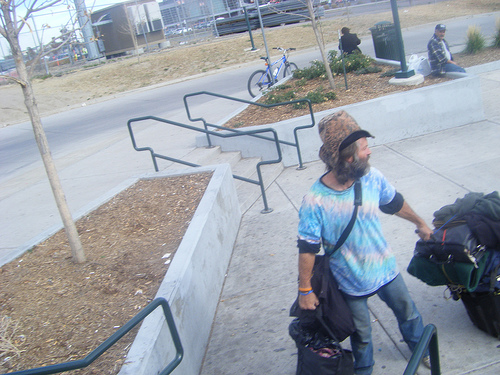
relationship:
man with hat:
[288, 94, 423, 362] [309, 113, 371, 167]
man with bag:
[288, 94, 423, 362] [275, 266, 353, 352]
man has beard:
[288, 94, 423, 362] [338, 145, 375, 190]